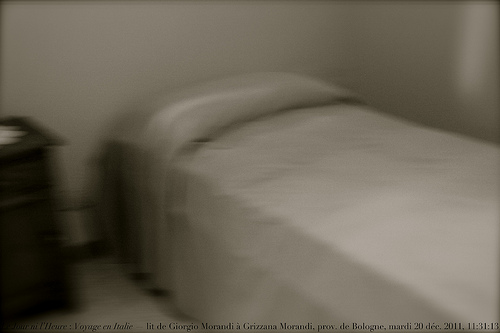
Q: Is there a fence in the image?
A: No, there are no fences.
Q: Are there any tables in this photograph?
A: Yes, there is a table.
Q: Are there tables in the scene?
A: Yes, there is a table.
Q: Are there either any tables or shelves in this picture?
A: Yes, there is a table.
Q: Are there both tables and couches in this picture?
A: No, there is a table but no couches.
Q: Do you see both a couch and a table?
A: No, there is a table but no couches.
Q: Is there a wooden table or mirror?
A: Yes, there is a wood table.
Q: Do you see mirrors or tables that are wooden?
A: Yes, the table is wooden.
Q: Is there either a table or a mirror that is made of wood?
A: Yes, the table is made of wood.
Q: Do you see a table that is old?
A: Yes, there is an old table.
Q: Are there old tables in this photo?
A: Yes, there is an old table.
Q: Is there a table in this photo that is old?
A: Yes, there is a table that is old.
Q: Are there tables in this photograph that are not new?
A: Yes, there is a old table.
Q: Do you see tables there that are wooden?
A: Yes, there is a wood table.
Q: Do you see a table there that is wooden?
A: Yes, there is a table that is wooden.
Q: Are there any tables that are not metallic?
A: Yes, there is a wooden table.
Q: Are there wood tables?
A: Yes, there is a table that is made of wood.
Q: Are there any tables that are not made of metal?
A: Yes, there is a table that is made of wood.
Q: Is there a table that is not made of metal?
A: Yes, there is a table that is made of wood.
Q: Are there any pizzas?
A: No, there are no pizzas.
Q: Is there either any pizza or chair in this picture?
A: No, there are no pizzas or chairs.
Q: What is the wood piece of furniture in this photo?
A: The piece of furniture is a table.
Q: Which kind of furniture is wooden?
A: The furniture is a table.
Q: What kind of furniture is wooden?
A: The furniture is a table.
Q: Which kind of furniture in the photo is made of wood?
A: The furniture is a table.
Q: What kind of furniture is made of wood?
A: The furniture is a table.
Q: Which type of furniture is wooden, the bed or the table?
A: The table is wooden.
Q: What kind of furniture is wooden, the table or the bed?
A: The table is wooden.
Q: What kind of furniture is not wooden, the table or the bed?
A: The bed is not wooden.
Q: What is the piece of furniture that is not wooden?
A: The piece of furniture is a bed.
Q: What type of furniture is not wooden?
A: The furniture is a bed.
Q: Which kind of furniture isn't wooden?
A: The furniture is a bed.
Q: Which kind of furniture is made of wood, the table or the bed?
A: The table is made of wood.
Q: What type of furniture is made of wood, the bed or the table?
A: The table is made of wood.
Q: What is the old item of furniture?
A: The piece of furniture is a table.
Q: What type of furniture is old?
A: The furniture is a table.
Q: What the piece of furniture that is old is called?
A: The piece of furniture is a table.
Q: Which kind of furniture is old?
A: The furniture is a table.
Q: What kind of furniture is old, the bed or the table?
A: The table is old.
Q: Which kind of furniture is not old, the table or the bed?
A: The bed is not old.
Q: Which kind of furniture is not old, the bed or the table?
A: The bed is not old.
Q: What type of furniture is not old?
A: The furniture is a bed.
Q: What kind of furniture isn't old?
A: The furniture is a bed.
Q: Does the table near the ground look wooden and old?
A: Yes, the table is wooden and old.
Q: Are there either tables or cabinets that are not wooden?
A: No, there is a table but it is wooden.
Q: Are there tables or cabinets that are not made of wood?
A: No, there is a table but it is made of wood.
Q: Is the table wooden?
A: Yes, the table is wooden.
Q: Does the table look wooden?
A: Yes, the table is wooden.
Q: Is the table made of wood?
A: Yes, the table is made of wood.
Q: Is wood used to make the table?
A: Yes, the table is made of wood.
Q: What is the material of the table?
A: The table is made of wood.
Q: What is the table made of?
A: The table is made of wood.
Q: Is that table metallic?
A: No, the table is wooden.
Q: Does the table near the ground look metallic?
A: No, the table is wooden.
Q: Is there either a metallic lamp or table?
A: No, there is a table but it is wooden.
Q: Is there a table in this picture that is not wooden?
A: No, there is a table but it is wooden.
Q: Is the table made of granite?
A: No, the table is made of wood.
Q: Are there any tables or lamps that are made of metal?
A: No, there is a table but it is made of wood.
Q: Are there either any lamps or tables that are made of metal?
A: No, there is a table but it is made of wood.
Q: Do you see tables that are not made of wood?
A: No, there is a table but it is made of wood.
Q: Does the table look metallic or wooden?
A: The table is wooden.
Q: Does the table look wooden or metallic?
A: The table is wooden.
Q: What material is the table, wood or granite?
A: The table is made of wood.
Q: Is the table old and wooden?
A: Yes, the table is old and wooden.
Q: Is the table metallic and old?
A: No, the table is old but wooden.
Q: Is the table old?
A: Yes, the table is old.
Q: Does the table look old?
A: Yes, the table is old.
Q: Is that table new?
A: No, the table is old.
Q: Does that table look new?
A: No, the table is old.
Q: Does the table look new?
A: No, the table is old.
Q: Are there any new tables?
A: No, there is a table but it is old.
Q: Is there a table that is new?
A: No, there is a table but it is old.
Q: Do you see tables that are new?
A: No, there is a table but it is old.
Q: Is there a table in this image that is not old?
A: No, there is a table but it is old.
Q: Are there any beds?
A: Yes, there is a bed.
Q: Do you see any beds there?
A: Yes, there is a bed.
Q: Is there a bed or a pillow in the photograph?
A: Yes, there is a bed.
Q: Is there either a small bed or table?
A: Yes, there is a small bed.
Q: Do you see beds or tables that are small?
A: Yes, the bed is small.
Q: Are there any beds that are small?
A: Yes, there is a small bed.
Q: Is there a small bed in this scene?
A: Yes, there is a small bed.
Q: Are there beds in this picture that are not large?
A: Yes, there is a small bed.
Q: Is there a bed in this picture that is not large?
A: Yes, there is a small bed.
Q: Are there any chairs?
A: No, there are no chairs.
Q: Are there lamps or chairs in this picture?
A: No, there are no chairs or lamps.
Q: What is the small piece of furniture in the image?
A: The piece of furniture is a bed.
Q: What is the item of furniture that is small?
A: The piece of furniture is a bed.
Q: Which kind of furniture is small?
A: The furniture is a bed.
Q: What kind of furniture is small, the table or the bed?
A: The bed is small.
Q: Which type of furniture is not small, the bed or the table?
A: The table is not small.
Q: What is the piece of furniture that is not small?
A: The piece of furniture is a table.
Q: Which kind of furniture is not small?
A: The furniture is a table.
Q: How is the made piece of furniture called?
A: The piece of furniture is a bed.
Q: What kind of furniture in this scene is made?
A: The furniture is a bed.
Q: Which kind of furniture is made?
A: The furniture is a bed.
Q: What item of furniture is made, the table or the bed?
A: The bed is made.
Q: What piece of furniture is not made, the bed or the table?
A: The table is not made.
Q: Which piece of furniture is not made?
A: The piece of furniture is a table.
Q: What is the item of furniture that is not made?
A: The piece of furniture is a table.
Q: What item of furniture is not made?
A: The piece of furniture is a table.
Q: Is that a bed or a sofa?
A: That is a bed.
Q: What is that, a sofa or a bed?
A: That is a bed.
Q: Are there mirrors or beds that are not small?
A: No, there is a bed but it is small.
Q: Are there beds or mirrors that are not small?
A: No, there is a bed but it is small.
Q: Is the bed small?
A: Yes, the bed is small.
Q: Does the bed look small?
A: Yes, the bed is small.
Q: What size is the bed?
A: The bed is small.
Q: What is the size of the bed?
A: The bed is small.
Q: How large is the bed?
A: The bed is small.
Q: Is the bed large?
A: No, the bed is small.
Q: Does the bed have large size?
A: No, the bed is small.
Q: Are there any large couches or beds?
A: No, there is a bed but it is small.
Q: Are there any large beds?
A: No, there is a bed but it is small.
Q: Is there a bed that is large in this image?
A: No, there is a bed but it is small.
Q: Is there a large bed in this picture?
A: No, there is a bed but it is small.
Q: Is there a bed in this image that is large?
A: No, there is a bed but it is small.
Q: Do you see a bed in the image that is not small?
A: No, there is a bed but it is small.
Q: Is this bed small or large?
A: The bed is small.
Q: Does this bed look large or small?
A: The bed is small.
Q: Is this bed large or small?
A: The bed is small.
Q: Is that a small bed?
A: Yes, that is a small bed.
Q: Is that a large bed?
A: No, that is a small bed.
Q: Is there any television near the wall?
A: No, there is a bed near the wall.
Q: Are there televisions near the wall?
A: No, there is a bed near the wall.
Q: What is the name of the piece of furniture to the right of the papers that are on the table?
A: The piece of furniture is a bed.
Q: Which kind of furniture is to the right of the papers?
A: The piece of furniture is a bed.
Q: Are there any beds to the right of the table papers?
A: Yes, there is a bed to the right of the papers.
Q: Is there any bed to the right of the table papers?
A: Yes, there is a bed to the right of the papers.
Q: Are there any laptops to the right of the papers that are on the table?
A: No, there is a bed to the right of the papers.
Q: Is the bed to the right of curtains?
A: No, the bed is to the right of the papers.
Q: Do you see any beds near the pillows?
A: Yes, there is a bed near the pillows.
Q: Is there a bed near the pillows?
A: Yes, there is a bed near the pillows.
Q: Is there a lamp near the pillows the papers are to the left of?
A: No, there is a bed near the pillows.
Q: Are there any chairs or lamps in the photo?
A: No, there are no chairs or lamps.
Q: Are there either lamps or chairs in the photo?
A: No, there are no chairs or lamps.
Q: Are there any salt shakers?
A: No, there are no salt shakers.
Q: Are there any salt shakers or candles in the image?
A: No, there are no salt shakers or candles.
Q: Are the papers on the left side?
A: Yes, the papers are on the left of the image.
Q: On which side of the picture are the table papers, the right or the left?
A: The papers are on the left of the image.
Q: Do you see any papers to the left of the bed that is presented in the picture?
A: Yes, there are papers to the left of the bed.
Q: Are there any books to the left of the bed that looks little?
A: No, there are papers to the left of the bed.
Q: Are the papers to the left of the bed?
A: Yes, the papers are to the left of the bed.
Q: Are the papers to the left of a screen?
A: No, the papers are to the left of the bed.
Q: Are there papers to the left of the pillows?
A: Yes, there are papers to the left of the pillows.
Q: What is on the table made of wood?
A: The papers are on the table.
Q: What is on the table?
A: The papers are on the table.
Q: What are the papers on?
A: The papers are on the table.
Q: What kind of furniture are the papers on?
A: The papers are on the table.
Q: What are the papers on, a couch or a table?
A: The papers are on a table.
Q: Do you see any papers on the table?
A: Yes, there are papers on the table.